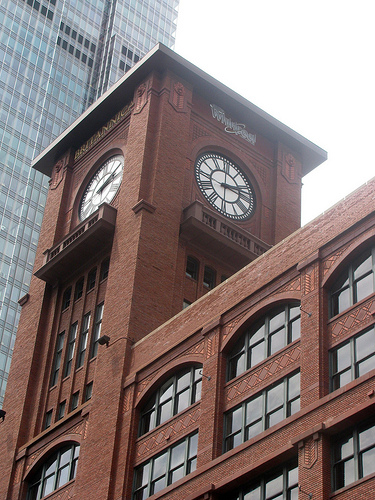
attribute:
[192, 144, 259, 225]
clock — black, white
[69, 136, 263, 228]
clocks — circular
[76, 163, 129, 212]
clock — black, white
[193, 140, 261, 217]
clock — white, black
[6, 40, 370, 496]
building — brick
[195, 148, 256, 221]
numbers — roman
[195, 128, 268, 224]
clock — indicating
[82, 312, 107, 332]
windows — rectangular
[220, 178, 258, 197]
hand — black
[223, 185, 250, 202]
hand — black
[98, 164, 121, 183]
hand — black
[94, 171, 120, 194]
hand — black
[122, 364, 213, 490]
window — arched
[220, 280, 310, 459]
window — arched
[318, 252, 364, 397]
window — arched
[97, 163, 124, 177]
hands — black